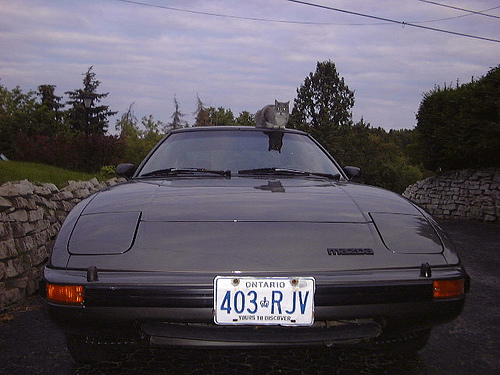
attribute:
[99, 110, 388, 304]
car — expensive, black, mazda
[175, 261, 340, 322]
license plate — canadian, white, lettered, ontario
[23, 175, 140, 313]
headlights — concealed, orange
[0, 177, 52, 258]
walls — rustic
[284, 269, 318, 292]
crown — small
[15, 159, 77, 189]
grass — covered, cut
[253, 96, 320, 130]
cat — gray, grey, white, laying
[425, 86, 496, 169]
hedge — green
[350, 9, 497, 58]
lines — above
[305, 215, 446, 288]
logo — mazda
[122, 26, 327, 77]
sky — cloudy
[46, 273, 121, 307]
lights — off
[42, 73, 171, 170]
trees — tall, green, conifer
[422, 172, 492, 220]
wall — stone, rock, short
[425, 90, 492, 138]
bushes — green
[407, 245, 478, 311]
light — signal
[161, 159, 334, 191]
wipers — auto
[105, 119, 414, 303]
corvette — black